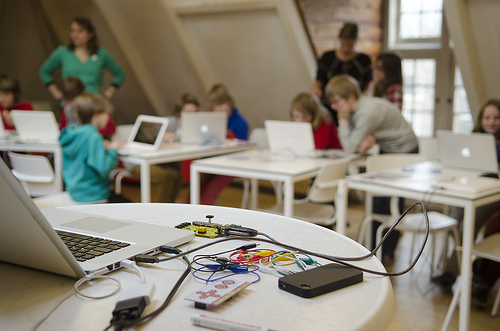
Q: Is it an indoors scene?
A: Yes, it is indoors.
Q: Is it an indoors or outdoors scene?
A: It is indoors.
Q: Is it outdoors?
A: No, it is indoors.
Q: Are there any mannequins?
A: No, there are no mannequins.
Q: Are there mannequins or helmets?
A: No, there are no mannequins or helmets.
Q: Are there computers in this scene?
A: Yes, there is a computer.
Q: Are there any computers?
A: Yes, there is a computer.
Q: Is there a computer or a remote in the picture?
A: Yes, there is a computer.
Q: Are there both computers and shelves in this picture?
A: No, there is a computer but no shelves.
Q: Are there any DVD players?
A: No, there are no DVD players.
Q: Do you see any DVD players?
A: No, there are no DVD players.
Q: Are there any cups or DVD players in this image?
A: No, there are no DVD players or cups.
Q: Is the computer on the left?
A: Yes, the computer is on the left of the image.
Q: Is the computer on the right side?
A: No, the computer is on the left of the image.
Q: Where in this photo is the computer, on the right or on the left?
A: The computer is on the left of the image.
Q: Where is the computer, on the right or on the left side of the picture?
A: The computer is on the left of the image.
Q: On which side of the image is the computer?
A: The computer is on the left of the image.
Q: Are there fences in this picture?
A: No, there are no fences.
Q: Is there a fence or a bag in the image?
A: No, there are no fences or bags.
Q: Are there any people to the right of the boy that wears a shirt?
A: Yes, there are people to the right of the boy.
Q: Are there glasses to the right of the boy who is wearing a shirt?
A: No, there are people to the right of the boy.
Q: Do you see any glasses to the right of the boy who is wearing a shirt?
A: No, there are people to the right of the boy.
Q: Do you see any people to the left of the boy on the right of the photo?
A: Yes, there are people to the left of the boy.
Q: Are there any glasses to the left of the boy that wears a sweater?
A: No, there are people to the left of the boy.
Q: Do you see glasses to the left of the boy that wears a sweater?
A: No, there are people to the left of the boy.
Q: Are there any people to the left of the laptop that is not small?
A: No, the people are to the right of the laptop.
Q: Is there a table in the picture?
A: Yes, there is a table.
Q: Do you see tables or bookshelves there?
A: Yes, there is a table.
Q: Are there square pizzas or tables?
A: Yes, there is a square table.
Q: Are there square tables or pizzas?
A: Yes, there is a square table.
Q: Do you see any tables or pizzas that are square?
A: Yes, the table is square.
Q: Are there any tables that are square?
A: Yes, there is a square table.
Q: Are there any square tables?
A: Yes, there is a square table.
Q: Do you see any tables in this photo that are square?
A: Yes, there is a table that is square.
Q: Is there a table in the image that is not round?
A: Yes, there is a square table.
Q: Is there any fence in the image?
A: No, there are no fences.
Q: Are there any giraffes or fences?
A: No, there are no fences or giraffes.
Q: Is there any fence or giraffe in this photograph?
A: No, there are no fences or giraffes.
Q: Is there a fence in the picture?
A: No, there are no fences.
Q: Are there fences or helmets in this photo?
A: No, there are no fences or helmets.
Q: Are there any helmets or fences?
A: No, there are no fences or helmets.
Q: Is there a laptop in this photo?
A: Yes, there is a laptop.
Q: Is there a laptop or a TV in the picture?
A: Yes, there is a laptop.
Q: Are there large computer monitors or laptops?
A: Yes, there is a large laptop.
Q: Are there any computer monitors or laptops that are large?
A: Yes, the laptop is large.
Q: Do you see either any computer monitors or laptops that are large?
A: Yes, the laptop is large.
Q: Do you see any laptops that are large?
A: Yes, there is a large laptop.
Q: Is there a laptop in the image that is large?
A: Yes, there is a laptop that is large.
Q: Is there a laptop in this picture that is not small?
A: Yes, there is a large laptop.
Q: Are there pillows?
A: No, there are no pillows.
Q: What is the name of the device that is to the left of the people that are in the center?
A: The device is a laptop.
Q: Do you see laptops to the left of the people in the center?
A: Yes, there is a laptop to the left of the people.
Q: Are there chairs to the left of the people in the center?
A: No, there is a laptop to the left of the people.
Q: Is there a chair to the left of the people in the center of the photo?
A: No, there is a laptop to the left of the people.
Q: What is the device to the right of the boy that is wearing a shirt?
A: The device is a laptop.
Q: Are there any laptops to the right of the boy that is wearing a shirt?
A: Yes, there is a laptop to the right of the boy.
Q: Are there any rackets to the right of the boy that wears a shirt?
A: No, there is a laptop to the right of the boy.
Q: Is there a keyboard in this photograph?
A: Yes, there is a keyboard.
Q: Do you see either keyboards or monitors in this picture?
A: Yes, there is a keyboard.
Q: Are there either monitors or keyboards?
A: Yes, there is a keyboard.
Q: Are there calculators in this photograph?
A: No, there are no calculators.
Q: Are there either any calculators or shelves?
A: No, there are no calculators or shelves.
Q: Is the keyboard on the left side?
A: Yes, the keyboard is on the left of the image.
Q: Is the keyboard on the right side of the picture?
A: No, the keyboard is on the left of the image.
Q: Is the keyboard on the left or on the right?
A: The keyboard is on the left of the image.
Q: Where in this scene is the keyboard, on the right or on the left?
A: The keyboard is on the left of the image.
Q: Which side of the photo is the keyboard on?
A: The keyboard is on the left of the image.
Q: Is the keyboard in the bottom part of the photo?
A: Yes, the keyboard is in the bottom of the image.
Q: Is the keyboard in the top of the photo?
A: No, the keyboard is in the bottom of the image.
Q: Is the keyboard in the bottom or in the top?
A: The keyboard is in the bottom of the image.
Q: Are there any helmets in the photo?
A: No, there are no helmets.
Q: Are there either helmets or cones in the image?
A: No, there are no helmets or cones.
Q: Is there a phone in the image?
A: Yes, there is a phone.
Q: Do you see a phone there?
A: Yes, there is a phone.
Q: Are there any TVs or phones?
A: Yes, there is a phone.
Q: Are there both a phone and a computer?
A: Yes, there are both a phone and a computer.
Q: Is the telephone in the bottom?
A: Yes, the telephone is in the bottom of the image.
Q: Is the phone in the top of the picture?
A: No, the phone is in the bottom of the image.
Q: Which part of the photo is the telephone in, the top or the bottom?
A: The telephone is in the bottom of the image.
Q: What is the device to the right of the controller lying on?
A: The phone is lying on the table.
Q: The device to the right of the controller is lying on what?
A: The phone is lying on the table.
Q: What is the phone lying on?
A: The phone is lying on the table.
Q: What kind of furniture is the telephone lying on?
A: The telephone is lying on the table.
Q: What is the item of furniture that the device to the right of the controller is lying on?
A: The piece of furniture is a table.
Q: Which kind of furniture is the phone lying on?
A: The telephone is lying on the table.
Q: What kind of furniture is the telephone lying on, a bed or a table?
A: The telephone is lying on a table.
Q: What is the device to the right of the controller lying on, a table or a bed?
A: The telephone is lying on a table.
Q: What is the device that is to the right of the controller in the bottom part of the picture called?
A: The device is a phone.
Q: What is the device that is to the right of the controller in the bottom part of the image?
A: The device is a phone.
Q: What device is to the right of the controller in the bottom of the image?
A: The device is a phone.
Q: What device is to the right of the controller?
A: The device is a phone.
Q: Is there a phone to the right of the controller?
A: Yes, there is a phone to the right of the controller.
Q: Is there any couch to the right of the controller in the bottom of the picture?
A: No, there is a phone to the right of the controller.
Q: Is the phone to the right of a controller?
A: Yes, the phone is to the right of a controller.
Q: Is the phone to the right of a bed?
A: No, the phone is to the right of a controller.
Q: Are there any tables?
A: Yes, there is a table.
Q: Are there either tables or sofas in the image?
A: Yes, there is a table.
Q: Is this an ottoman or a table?
A: This is a table.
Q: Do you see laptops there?
A: Yes, there is a laptop.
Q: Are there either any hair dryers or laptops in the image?
A: Yes, there is a laptop.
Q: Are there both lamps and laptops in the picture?
A: No, there is a laptop but no lamps.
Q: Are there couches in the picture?
A: No, there are no couches.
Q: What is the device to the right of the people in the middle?
A: The device is a laptop.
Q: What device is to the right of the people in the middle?
A: The device is a laptop.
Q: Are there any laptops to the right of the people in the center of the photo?
A: Yes, there is a laptop to the right of the people.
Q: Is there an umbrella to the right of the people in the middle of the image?
A: No, there is a laptop to the right of the people.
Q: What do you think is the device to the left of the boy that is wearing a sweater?
A: The device is a laptop.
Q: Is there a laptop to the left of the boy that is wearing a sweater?
A: Yes, there is a laptop to the left of the boy.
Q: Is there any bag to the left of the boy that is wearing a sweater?
A: No, there is a laptop to the left of the boy.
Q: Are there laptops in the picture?
A: Yes, there is a laptop.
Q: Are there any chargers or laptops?
A: Yes, there is a laptop.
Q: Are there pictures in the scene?
A: No, there are no pictures.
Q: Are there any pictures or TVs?
A: No, there are no pictures or tvs.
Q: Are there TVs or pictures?
A: No, there are no pictures or tvs.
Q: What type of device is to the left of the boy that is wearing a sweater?
A: The device is a laptop.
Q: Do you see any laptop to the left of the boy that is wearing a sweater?
A: Yes, there is a laptop to the left of the boy.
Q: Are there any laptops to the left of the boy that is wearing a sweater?
A: Yes, there is a laptop to the left of the boy.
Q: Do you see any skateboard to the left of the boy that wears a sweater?
A: No, there is a laptop to the left of the boy.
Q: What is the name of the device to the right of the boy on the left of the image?
A: The device is a laptop.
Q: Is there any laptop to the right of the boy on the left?
A: Yes, there is a laptop to the right of the boy.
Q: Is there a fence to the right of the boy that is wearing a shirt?
A: No, there is a laptop to the right of the boy.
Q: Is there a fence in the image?
A: No, there are no fences.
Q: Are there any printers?
A: No, there are no printers.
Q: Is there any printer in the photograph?
A: No, there are no printers.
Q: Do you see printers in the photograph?
A: No, there are no printers.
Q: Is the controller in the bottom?
A: Yes, the controller is in the bottom of the image.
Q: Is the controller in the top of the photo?
A: No, the controller is in the bottom of the image.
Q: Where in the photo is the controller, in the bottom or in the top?
A: The controller is in the bottom of the image.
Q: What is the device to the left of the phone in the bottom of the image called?
A: The device is a controller.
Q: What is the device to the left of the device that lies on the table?
A: The device is a controller.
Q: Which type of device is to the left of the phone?
A: The device is a controller.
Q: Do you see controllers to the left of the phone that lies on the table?
A: Yes, there is a controller to the left of the phone.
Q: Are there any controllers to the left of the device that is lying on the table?
A: Yes, there is a controller to the left of the phone.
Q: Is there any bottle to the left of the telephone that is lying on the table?
A: No, there is a controller to the left of the telephone.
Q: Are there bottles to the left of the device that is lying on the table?
A: No, there is a controller to the left of the telephone.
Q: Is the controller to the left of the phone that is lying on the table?
A: Yes, the controller is to the left of the telephone.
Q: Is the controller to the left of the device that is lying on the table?
A: Yes, the controller is to the left of the telephone.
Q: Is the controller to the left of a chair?
A: No, the controller is to the left of the telephone.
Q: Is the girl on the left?
A: Yes, the girl is on the left of the image.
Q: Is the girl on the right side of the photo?
A: No, the girl is on the left of the image.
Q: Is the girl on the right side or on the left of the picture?
A: The girl is on the left of the image.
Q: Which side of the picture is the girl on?
A: The girl is on the left of the image.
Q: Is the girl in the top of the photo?
A: Yes, the girl is in the top of the image.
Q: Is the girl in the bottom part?
A: No, the girl is in the top of the image.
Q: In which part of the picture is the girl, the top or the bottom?
A: The girl is in the top of the image.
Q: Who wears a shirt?
A: The girl wears a shirt.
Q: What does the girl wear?
A: The girl wears a shirt.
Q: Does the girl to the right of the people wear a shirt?
A: Yes, the girl wears a shirt.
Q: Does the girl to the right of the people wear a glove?
A: No, the girl wears a shirt.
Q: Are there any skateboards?
A: No, there are no skateboards.